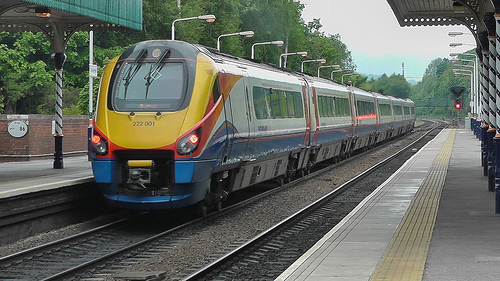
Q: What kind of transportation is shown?
A: Train.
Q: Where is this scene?
A: Train station.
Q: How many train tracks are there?
A: Two.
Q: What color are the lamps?
A: White.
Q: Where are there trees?
A: Outside the station.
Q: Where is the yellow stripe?
A: On the station platform.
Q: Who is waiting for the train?
A: No one.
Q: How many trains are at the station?
A: One.